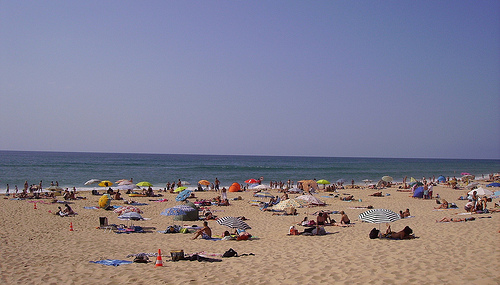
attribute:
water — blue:
[0, 150, 495, 197]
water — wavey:
[13, 152, 498, 184]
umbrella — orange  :
[194, 177, 212, 187]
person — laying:
[186, 221, 211, 242]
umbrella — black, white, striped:
[359, 208, 401, 225]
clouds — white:
[126, 38, 216, 104]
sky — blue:
[1, 3, 488, 133]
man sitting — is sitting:
[96, 190, 113, 212]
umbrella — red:
[243, 173, 261, 195]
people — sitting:
[189, 217, 253, 242]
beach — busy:
[2, 169, 498, 284]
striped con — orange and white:
[152, 247, 165, 268]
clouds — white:
[14, 71, 473, 143]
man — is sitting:
[414, 178, 426, 197]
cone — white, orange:
[149, 244, 171, 269]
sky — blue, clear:
[2, 2, 494, 159]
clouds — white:
[2, 78, 329, 153]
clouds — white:
[111, 103, 157, 139]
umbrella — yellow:
[130, 177, 151, 187]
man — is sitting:
[383, 222, 393, 234]